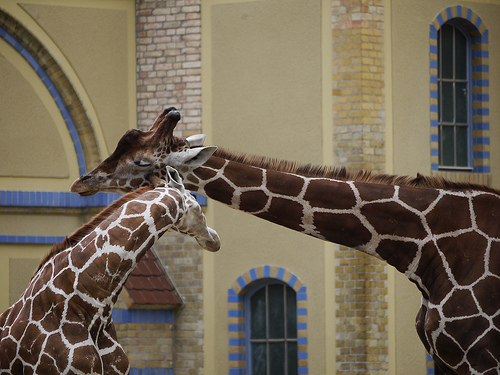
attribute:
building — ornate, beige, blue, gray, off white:
[2, 1, 498, 371]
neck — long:
[190, 140, 417, 261]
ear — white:
[174, 147, 220, 169]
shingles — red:
[117, 232, 189, 309]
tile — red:
[122, 251, 185, 311]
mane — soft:
[176, 134, 496, 194]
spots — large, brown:
[383, 188, 496, 259]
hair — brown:
[216, 140, 478, 198]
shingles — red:
[135, 254, 182, 315]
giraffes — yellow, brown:
[2, 113, 497, 374]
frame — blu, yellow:
[225, 263, 311, 373]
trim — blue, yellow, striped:
[226, 263, 308, 369]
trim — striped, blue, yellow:
[427, 4, 492, 172]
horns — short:
[145, 101, 184, 153]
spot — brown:
[430, 223, 491, 290]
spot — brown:
[422, 184, 469, 234]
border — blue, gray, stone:
[217, 264, 313, 373]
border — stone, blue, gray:
[426, 12, 495, 177]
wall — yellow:
[1, 6, 499, 369]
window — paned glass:
[242, 279, 294, 373]